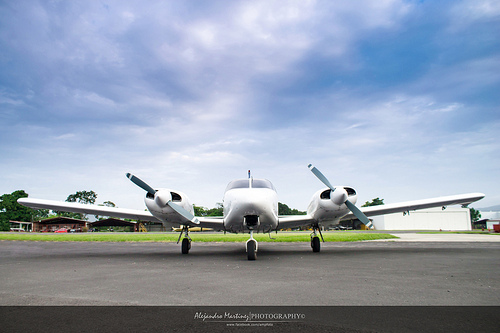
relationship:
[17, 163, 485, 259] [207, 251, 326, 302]
airplane on asphalt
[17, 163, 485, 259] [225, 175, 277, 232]
airplane has cockpit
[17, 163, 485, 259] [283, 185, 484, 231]
airplane has wing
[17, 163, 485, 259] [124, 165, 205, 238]
airplane has engine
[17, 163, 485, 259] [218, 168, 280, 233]
airplane has cockpit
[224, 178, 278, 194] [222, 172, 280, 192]
windows on cockpit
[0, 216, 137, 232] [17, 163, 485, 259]
buildings behind airplane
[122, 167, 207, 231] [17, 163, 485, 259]
propeller on airplane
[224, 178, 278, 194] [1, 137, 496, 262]
windows on airplane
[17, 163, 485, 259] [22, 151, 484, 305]
airplane at airport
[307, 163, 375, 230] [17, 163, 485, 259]
blades on airplane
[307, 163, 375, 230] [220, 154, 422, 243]
blades are on airplane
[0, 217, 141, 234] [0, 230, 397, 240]
buildings are behind grass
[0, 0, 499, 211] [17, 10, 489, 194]
sky in sky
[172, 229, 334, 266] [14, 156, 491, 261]
tires are on airplane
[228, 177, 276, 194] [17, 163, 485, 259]
windows are on airplane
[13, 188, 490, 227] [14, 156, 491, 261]
wings are on airplane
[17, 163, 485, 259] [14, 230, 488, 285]
airplane are on cement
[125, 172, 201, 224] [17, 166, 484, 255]
propeller are on airplane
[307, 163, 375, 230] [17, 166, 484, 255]
blades are on airplane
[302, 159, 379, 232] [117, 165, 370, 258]
blades are on propellors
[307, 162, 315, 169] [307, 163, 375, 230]
stripe on blades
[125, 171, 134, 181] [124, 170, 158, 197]
stripe on blade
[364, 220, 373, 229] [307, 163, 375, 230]
stripe on blades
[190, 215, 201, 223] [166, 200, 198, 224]
stripe on blade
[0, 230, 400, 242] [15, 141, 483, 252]
grass behind airplane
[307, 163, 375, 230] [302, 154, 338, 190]
blades has blade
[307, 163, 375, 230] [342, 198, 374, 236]
blades has blade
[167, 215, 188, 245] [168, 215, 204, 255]
hatch in landing gear